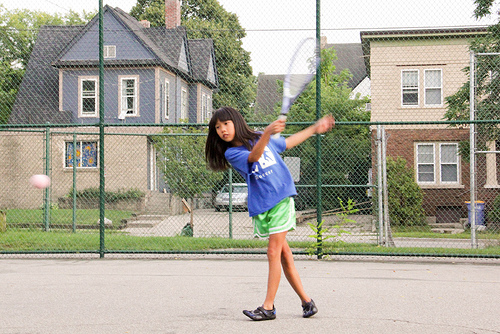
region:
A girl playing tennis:
[150, 32, 374, 324]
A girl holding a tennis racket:
[179, 21, 361, 213]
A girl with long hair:
[161, 80, 322, 211]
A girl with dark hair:
[180, 85, 283, 182]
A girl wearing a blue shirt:
[169, 81, 335, 249]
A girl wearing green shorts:
[187, 91, 324, 285]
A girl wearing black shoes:
[178, 100, 335, 330]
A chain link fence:
[55, 54, 160, 234]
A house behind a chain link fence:
[16, 20, 210, 265]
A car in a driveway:
[175, 163, 261, 240]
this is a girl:
[200, 93, 334, 323]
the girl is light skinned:
[267, 261, 281, 287]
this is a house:
[54, 26, 162, 138]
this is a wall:
[372, 56, 401, 109]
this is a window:
[424, 68, 446, 105]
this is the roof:
[147, 23, 174, 55]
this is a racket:
[285, 49, 314, 97]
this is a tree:
[213, 1, 253, 90]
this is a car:
[218, 179, 245, 211]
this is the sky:
[253, 11, 295, 61]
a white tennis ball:
[27, 164, 84, 199]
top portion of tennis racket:
[283, 42, 338, 99]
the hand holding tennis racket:
[267, 100, 289, 143]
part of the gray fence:
[378, 122, 461, 242]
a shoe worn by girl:
[242, 302, 277, 321]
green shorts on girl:
[252, 210, 297, 230]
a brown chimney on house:
[165, 0, 188, 35]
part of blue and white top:
[254, 159, 300, 201]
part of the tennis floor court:
[12, 267, 159, 328]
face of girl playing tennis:
[205, 115, 247, 145]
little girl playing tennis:
[194, 24, 365, 318]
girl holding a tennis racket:
[281, 35, 327, 115]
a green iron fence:
[351, 45, 496, 236]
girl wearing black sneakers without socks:
[237, 292, 327, 325]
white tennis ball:
[23, 163, 62, 205]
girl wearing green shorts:
[248, 200, 304, 237]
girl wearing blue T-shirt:
[217, 137, 317, 204]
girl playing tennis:
[193, 28, 373, 318]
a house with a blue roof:
[18, 31, 210, 123]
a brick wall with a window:
[404, 130, 471, 190]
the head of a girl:
[211, 104, 245, 146]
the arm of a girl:
[222, 131, 271, 171]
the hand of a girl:
[266, 113, 288, 138]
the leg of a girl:
[256, 201, 291, 306]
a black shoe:
[237, 300, 282, 325]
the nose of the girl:
[216, 123, 227, 134]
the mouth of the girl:
[220, 129, 232, 140]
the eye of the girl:
[221, 116, 228, 128]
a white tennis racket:
[266, 35, 327, 145]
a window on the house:
[118, 72, 140, 117]